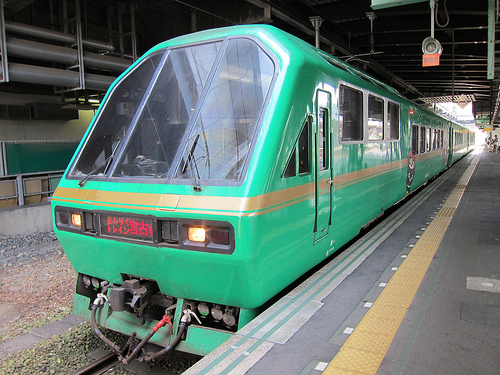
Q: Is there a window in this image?
A: Yes, there is a window.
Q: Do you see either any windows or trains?
A: Yes, there is a window.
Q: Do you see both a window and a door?
A: Yes, there are both a window and a door.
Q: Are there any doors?
A: Yes, there is a door.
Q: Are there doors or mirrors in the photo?
A: Yes, there is a door.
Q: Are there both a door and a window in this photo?
A: Yes, there are both a door and a window.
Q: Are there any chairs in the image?
A: No, there are no chairs.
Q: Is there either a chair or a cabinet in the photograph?
A: No, there are no chairs or cabinets.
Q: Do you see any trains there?
A: Yes, there is a train.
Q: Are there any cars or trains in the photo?
A: Yes, there is a train.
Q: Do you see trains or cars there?
A: Yes, there is a train.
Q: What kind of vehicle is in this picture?
A: The vehicle is a train.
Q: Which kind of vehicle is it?
A: The vehicle is a train.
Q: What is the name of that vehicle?
A: That is a train.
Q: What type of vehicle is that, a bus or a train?
A: That is a train.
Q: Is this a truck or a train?
A: This is a train.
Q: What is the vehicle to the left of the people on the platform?
A: The vehicle is a train.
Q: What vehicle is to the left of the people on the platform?
A: The vehicle is a train.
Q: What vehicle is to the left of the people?
A: The vehicle is a train.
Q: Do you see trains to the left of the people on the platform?
A: Yes, there is a train to the left of the people.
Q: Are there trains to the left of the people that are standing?
A: Yes, there is a train to the left of the people.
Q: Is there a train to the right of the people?
A: No, the train is to the left of the people.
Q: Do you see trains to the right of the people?
A: No, the train is to the left of the people.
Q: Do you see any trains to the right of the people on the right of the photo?
A: No, the train is to the left of the people.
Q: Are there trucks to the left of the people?
A: No, there is a train to the left of the people.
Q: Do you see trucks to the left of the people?
A: No, there is a train to the left of the people.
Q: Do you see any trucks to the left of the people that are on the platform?
A: No, there is a train to the left of the people.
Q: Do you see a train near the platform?
A: Yes, there is a train near the platform.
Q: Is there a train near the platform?
A: Yes, there is a train near the platform.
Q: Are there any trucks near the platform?
A: No, there is a train near the platform.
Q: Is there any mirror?
A: No, there are no mirrors.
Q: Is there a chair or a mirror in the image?
A: No, there are no mirrors or chairs.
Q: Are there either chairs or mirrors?
A: No, there are no mirrors or chairs.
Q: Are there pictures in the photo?
A: No, there are no pictures.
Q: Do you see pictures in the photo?
A: No, there are no pictures.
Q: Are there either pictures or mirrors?
A: No, there are no pictures or mirrors.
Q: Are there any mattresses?
A: No, there are no mattresses.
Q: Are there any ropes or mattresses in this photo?
A: No, there are no mattresses or ropes.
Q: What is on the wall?
A: The pipes are on the wall.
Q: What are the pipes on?
A: The pipes are on the wall.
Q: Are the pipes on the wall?
A: Yes, the pipes are on the wall.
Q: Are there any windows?
A: Yes, there is a window.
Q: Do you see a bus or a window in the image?
A: Yes, there is a window.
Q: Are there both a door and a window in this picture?
A: Yes, there are both a window and a door.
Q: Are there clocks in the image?
A: No, there are no clocks.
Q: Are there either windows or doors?
A: Yes, there is a window.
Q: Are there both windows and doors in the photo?
A: Yes, there are both a window and doors.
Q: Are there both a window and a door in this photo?
A: Yes, there are both a window and a door.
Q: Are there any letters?
A: Yes, there are letters.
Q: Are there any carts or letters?
A: Yes, there are letters.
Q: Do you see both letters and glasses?
A: No, there are letters but no glasses.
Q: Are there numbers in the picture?
A: No, there are no numbers.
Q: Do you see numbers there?
A: No, there are no numbers.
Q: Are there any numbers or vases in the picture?
A: No, there are no numbers or vases.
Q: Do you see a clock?
A: No, there are no clocks.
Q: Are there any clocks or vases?
A: No, there are no clocks or vases.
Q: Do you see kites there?
A: No, there are no kites.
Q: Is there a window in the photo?
A: Yes, there is a window.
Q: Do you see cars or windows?
A: Yes, there is a window.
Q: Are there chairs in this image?
A: No, there are no chairs.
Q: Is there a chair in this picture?
A: No, there are no chairs.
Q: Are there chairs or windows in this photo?
A: Yes, there is a window.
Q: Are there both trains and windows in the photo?
A: Yes, there are both a window and a train.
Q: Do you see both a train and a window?
A: Yes, there are both a window and a train.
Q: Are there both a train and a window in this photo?
A: Yes, there are both a window and a train.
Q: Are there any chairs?
A: No, there are no chairs.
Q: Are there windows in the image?
A: Yes, there is a window.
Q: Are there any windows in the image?
A: Yes, there is a window.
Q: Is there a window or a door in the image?
A: Yes, there is a window.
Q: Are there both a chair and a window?
A: No, there is a window but no chairs.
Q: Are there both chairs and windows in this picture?
A: No, there is a window but no chairs.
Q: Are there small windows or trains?
A: Yes, there is a small window.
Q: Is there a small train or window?
A: Yes, there is a small window.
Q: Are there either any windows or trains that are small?
A: Yes, the window is small.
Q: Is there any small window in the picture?
A: Yes, there is a small window.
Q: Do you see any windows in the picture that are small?
A: Yes, there is a small window.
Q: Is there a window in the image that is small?
A: Yes, there is a window that is small.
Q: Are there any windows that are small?
A: Yes, there is a window that is small.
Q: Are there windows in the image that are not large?
A: Yes, there is a small window.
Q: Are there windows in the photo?
A: Yes, there is a window.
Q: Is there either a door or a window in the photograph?
A: Yes, there is a window.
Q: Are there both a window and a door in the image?
A: Yes, there are both a window and a door.